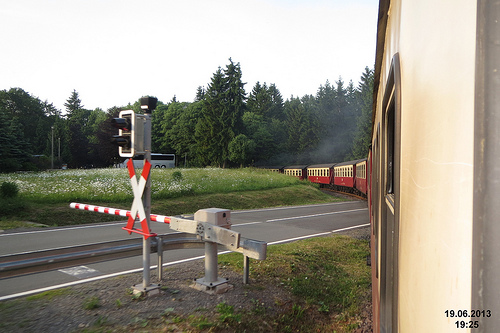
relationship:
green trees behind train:
[148, 60, 327, 169] [270, 0, 406, 330]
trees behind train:
[22, 77, 299, 156] [284, 159, 374, 199]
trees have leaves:
[227, 132, 259, 168] [188, 55, 257, 164]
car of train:
[305, 163, 332, 185] [254, 0, 499, 332]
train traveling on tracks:
[263, 164, 451, 194] [330, 168, 389, 296]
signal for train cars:
[115, 107, 152, 161] [286, 162, 381, 208]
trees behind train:
[227, 132, 259, 168] [249, 0, 499, 330]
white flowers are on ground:
[0, 165, 249, 197] [1, 159, 376, 331]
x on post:
[122, 154, 154, 241] [142, 113, 152, 286]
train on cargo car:
[254, 0, 499, 332] [305, 162, 334, 188]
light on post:
[96, 84, 244, 205] [139, 111, 155, 294]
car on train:
[302, 159, 334, 187] [254, 90, 405, 245]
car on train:
[305, 163, 332, 185] [254, 90, 405, 245]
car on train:
[305, 163, 332, 185] [254, 0, 499, 332]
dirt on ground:
[1, 256, 287, 331] [1, 159, 376, 331]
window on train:
[326, 168, 331, 178] [300, 159, 374, 196]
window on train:
[308, 168, 313, 178] [300, 159, 374, 196]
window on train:
[322, 168, 333, 184] [300, 159, 374, 196]